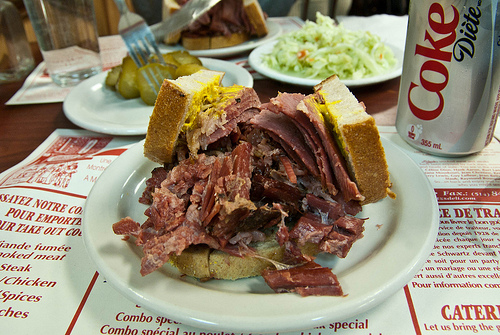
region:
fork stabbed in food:
[110, 6, 171, 67]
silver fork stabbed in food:
[104, 5, 169, 68]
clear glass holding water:
[38, 3, 98, 98]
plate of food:
[100, 75, 429, 306]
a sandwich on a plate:
[124, 87, 418, 313]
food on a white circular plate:
[86, 106, 456, 330]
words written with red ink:
[0, 178, 90, 247]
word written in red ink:
[407, 13, 456, 138]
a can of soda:
[398, 6, 498, 155]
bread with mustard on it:
[313, 65, 380, 214]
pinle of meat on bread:
[135, 92, 348, 287]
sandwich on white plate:
[85, 81, 426, 319]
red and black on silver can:
[397, 4, 499, 154]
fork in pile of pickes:
[105, 2, 194, 99]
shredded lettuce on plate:
[252, 17, 402, 87]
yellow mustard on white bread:
[182, 81, 227, 124]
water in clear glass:
[28, 1, 100, 84]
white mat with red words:
[1, 127, 498, 332]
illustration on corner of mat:
[12, 130, 107, 194]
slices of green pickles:
[105, 50, 198, 105]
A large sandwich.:
[114, 86, 396, 283]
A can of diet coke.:
[377, 9, 495, 149]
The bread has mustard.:
[154, 79, 241, 113]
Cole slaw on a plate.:
[282, 32, 360, 69]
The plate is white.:
[204, 302, 265, 319]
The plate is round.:
[62, 103, 464, 331]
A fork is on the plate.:
[105, 13, 183, 98]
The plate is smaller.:
[240, 23, 425, 110]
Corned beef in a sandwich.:
[207, 143, 357, 237]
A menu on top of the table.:
[20, 186, 65, 286]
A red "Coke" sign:
[397, 3, 463, 128]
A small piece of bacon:
[263, 255, 340, 307]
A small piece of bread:
[139, 79, 179, 164]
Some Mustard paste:
[318, 95, 334, 122]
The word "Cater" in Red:
[436, 300, 498, 326]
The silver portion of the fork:
[115, 8, 167, 86]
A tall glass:
[23, 0, 104, 94]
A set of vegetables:
[273, 8, 386, 76]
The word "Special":
[325, 315, 380, 332]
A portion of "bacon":
[180, 162, 271, 242]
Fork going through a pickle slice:
[113, 5, 180, 97]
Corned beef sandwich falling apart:
[118, 68, 401, 283]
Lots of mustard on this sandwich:
[148, 67, 381, 208]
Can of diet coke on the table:
[391, 1, 498, 158]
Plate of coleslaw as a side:
[250, 10, 403, 85]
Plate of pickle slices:
[60, 46, 260, 142]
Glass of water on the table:
[21, 0, 108, 89]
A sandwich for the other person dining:
[136, 0, 285, 54]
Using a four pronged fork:
[116, 9, 179, 108]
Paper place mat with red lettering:
[1, 114, 498, 333]